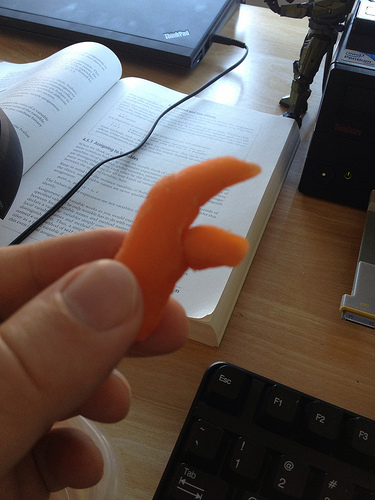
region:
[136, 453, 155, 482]
part of a floor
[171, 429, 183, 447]
edge of a kryboar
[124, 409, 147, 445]
part of a floor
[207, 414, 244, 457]
part of a keyboard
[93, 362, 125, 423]
part of a finger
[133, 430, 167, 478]
part of a floor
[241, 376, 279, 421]
part of a keyboard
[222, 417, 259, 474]
part of a button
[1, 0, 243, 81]
Black laptop sitting on a wooden desk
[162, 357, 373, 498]
Black keyboard sitting on a wooden desk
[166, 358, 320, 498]
Black keyboard with white lettering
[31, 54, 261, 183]
Black and white open text book with a wire across it's page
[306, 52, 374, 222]
Black computer with a small green light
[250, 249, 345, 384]
Top of wooden desk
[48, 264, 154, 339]
Pink human finger nail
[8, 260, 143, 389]
Thumb of a human being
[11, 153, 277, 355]
Human hand holding a forked orange object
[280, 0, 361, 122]
Figurine standing on a wooden desk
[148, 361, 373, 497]
Black keyboard on table.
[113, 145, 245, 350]
Orange carrot in fingers.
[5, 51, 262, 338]
Book on the table.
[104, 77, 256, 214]
Black printed words on a page.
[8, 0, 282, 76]
Black laptop on table.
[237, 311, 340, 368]
Wood grain on table.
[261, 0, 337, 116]
Character figure on table.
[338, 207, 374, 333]
Electronic plug in on table.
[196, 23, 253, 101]
Black cord plugged into computer.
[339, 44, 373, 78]
Blue writing on electronics.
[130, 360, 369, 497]
The keyboard is black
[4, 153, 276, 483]
A hand holding food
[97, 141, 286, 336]
Orange piece of food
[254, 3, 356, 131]
Green figurine leaning against the computer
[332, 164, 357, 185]
The power light is green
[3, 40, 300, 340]
The book is open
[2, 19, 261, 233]
The cord is black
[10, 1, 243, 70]
The laptop is black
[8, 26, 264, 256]
The cord is attached to the laptop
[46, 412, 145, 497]
Plastic bag on the desk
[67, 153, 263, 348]
a man is holding a carrot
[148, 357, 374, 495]
a keyboard is on the table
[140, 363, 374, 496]
the keyboard is black with white markings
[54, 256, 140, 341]
the man's fingernail is manicured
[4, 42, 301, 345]
a book is open on the desk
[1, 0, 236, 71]
a laptop is closed on the table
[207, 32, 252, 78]
a wire is plugged into the laptop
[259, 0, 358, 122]
a star wars figure is in the table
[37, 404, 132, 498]
a plastic bag is under the man's hand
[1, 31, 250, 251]
a headset is plugged into the laptop